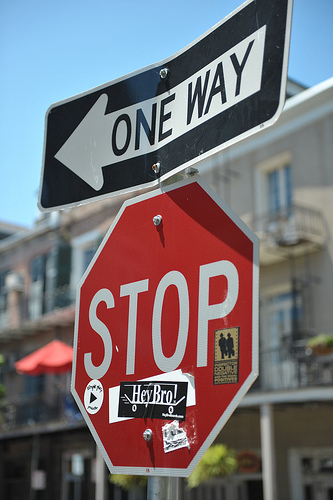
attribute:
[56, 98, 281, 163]
arrow — white, pointing left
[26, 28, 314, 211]
sign — black, red, white, black &white, one way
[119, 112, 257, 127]
words — one way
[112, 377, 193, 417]
sticker — black, white, round, saying hey bro, adundant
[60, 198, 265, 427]
sign — red, white, stop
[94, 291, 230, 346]
white letters — stop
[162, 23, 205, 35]
sky — blue, clear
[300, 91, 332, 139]
building — blurry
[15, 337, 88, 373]
red umbrella — open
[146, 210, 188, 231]
bolt — silver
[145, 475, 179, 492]
pole — silver, gray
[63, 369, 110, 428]
sticker — round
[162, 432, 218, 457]
decal — torn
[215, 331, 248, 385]
sticker — black, gold